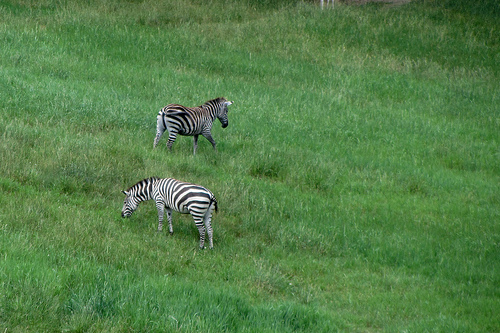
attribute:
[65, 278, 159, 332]
grass — thick, green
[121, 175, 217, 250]
zebra — grazing, running, small, walking, striped, bent, eating, sideways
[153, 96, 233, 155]
zebra — uphill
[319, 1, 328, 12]
trunk — thin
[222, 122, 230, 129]
nose — black